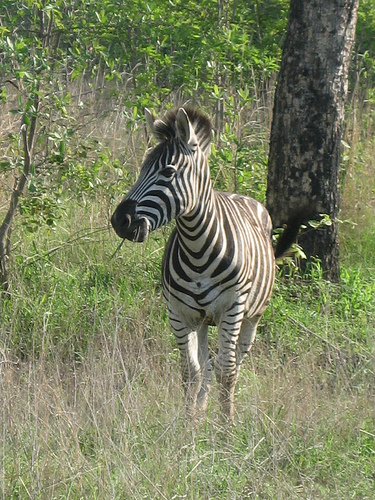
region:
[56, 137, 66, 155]
a green tree leaf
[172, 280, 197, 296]
a black zebra strip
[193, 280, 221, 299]
a black zebra strip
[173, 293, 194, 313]
a black zebra strip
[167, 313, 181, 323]
a black zebra strip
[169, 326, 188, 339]
a black zebra strip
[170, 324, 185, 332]
a black zebra strip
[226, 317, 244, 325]
a black zebra strip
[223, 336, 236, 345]
a black zebra strip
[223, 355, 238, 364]
a black zebra strip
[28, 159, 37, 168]
a green tree leaf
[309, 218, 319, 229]
a green tree leaf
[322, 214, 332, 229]
a green tree leaf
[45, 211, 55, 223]
a green tree leaf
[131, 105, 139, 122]
a green tree leaf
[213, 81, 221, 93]
a green tree leaf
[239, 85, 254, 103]
a green tree leaf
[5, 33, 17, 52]
a green tree leaf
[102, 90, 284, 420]
A zebra in a field.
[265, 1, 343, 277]
A small tree trunk.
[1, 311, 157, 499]
Tall, yellow grass in the field.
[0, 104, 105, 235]
A small tree with light foliage.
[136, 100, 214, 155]
A strange protrusion of hair on the zebra's head.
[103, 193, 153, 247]
A black equine snout.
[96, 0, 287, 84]
Dense foliage above the zebra.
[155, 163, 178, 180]
The glazed eye of the zebra.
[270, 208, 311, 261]
The zebra swishes its black tail.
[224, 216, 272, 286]
Black and white stripe pattern on the zebra's body.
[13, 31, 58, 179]
a tree in a distance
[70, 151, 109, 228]
a tree in a distance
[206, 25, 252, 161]
a tree in a distance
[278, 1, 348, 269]
a tree in a distance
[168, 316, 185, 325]
a black strip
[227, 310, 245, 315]
a black strip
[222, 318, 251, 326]
a black strip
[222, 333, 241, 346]
a black strip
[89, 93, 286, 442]
This is a young zebra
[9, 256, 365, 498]
Grass is up to zebra's knees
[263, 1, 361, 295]
This tree is older than the other trees pictures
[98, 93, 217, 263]
This zebra is looking to the left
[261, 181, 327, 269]
Zebra's tail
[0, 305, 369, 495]
The grass is dead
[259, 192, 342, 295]
Weeds grow around the tree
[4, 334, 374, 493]
A field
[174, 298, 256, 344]
Zebra's under belly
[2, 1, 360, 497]
The weather is sunny